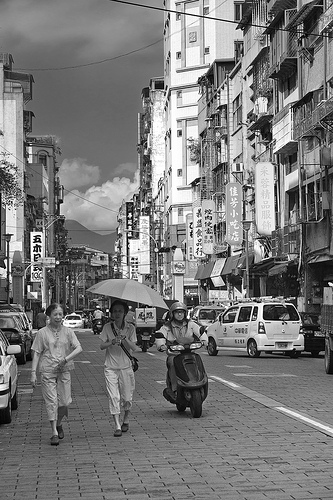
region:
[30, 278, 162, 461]
two women walking down the street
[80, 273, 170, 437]
a woman holding an umbrella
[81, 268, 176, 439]
an Asian woman holding an umbrella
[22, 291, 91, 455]
an Asian woman walking down the street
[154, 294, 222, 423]
a man riding a moped down the street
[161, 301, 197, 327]
a man wearing a helmet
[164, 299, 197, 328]
a man wearing glasses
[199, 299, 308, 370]
a white van pulling onto a city street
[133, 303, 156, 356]
the back of a motorcycle with cargo on back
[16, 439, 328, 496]
paving stones used to make the street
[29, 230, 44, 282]
A large business sign.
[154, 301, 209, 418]
A man riding a scooter.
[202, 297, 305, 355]
A white minivan with writing on the side.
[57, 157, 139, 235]
A large formation of white clouds in the distance.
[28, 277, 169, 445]
Two women walking on the sidewalk.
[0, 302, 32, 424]
Cars parked on the side of the street.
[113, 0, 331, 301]
A row of multistory buildings.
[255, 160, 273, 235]
A large white sign with Japanese writing on it.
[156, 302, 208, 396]
The man is wearing a jacket and helmet.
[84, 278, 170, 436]
The woman is carrying an umbrella.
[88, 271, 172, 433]
person holding an umbrela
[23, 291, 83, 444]
old grand ma walking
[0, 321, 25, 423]
white car that is parked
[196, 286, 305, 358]
white and black van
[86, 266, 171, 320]
solid umbrella in grey scale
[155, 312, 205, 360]
grey and black jacket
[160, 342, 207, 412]
black and dark grey motorcycle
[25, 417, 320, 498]
brick sidewalk in grey scale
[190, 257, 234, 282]
grey and white sign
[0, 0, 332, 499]
The image is black and white.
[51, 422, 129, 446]
Four feet are in shoes.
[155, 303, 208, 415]
A man is on a motorscooter.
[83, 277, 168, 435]
A womanis carying an umbrella.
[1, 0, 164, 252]
Some clouds are in the sky.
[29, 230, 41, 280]
Oriental writing on a sign.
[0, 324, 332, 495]
The street is paved in bricks.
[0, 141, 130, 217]
A wire is in the air.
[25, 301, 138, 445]
Two women are walkig in the street.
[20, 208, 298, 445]
a busy Asian street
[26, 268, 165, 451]
two women walking down the street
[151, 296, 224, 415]
a moped traveling down the street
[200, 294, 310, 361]
a van pulling out into the street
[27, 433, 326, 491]
a street made from paving stones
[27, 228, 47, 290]
a sign outside a business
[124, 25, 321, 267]
the facade of several city buildings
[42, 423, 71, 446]
the feet of a woman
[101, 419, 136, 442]
the feet of a woman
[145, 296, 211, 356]
a man riding a moped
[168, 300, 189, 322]
helmet is on the man's head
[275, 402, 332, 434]
white line is on the road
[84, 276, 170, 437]
woman is carrying an umbrella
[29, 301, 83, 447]
the woman is walking down the street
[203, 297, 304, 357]
the van is white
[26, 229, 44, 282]
the sign has black letters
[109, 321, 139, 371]
the purse is across the woman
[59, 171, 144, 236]
the cloud is white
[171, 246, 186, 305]
the clock tower is white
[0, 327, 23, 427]
the car is parked on the side of the road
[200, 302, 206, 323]
a vehicle on the road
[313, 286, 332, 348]
a vehicle on the road